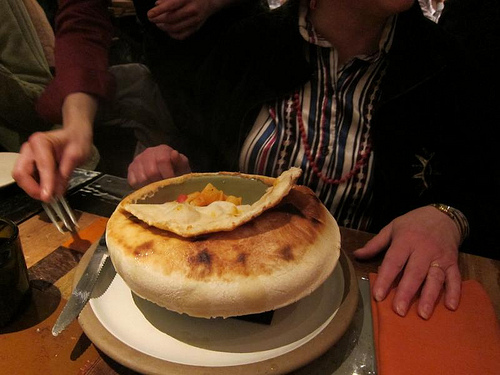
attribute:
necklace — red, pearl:
[297, 67, 409, 195]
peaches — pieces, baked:
[155, 178, 263, 215]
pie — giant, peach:
[102, 170, 349, 327]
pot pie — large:
[104, 166, 341, 319]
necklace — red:
[254, 31, 379, 187]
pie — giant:
[107, 160, 344, 335]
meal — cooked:
[95, 151, 350, 370]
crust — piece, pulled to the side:
[131, 159, 311, 243]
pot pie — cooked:
[125, 158, 327, 322]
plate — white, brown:
[80, 238, 353, 369]